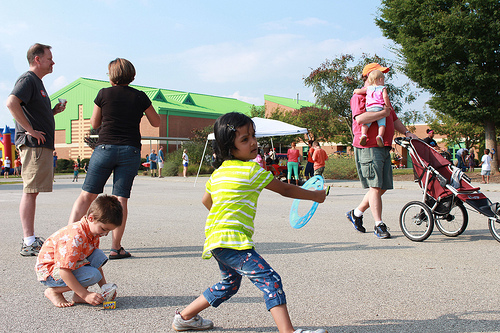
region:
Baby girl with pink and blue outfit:
[361, 68, 391, 152]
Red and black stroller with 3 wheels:
[393, 133, 496, 248]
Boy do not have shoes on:
[38, 191, 128, 311]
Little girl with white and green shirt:
[204, 105, 286, 257]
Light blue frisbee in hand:
[287, 170, 332, 236]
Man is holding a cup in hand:
[7, 44, 70, 256]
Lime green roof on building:
[146, 79, 253, 116]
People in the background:
[283, 138, 331, 180]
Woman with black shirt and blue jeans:
[68, 48, 157, 193]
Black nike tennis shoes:
[344, 204, 397, 241]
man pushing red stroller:
[329, 55, 499, 230]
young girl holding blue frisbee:
[185, 120, 340, 322]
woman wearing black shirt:
[65, 57, 162, 265]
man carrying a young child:
[343, 58, 407, 239]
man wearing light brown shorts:
[3, 37, 65, 258]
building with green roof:
[35, 76, 261, 170]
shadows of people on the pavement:
[121, 219, 488, 331]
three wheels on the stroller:
[402, 194, 497, 235]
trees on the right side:
[301, 3, 488, 167]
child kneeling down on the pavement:
[30, 204, 126, 311]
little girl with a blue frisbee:
[163, 105, 328, 331]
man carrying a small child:
[345, 55, 405, 239]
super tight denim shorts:
[72, 139, 142, 197]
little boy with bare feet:
[26, 191, 130, 313]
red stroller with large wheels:
[390, 128, 499, 248]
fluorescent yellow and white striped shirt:
[187, 156, 274, 258]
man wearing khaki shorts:
[2, 40, 69, 256]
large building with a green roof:
[26, 71, 325, 173]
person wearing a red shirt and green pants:
[277, 138, 305, 187]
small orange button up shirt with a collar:
[24, 217, 100, 284]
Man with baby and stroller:
[345, 59, 496, 247]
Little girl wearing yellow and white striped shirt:
[192, 111, 290, 263]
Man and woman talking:
[8, 43, 160, 188]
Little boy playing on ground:
[28, 193, 137, 313]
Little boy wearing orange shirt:
[25, 189, 120, 280]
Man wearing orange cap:
[356, 53, 392, 84]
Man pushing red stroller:
[351, 56, 496, 248]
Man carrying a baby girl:
[352, 56, 393, 149]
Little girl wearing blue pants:
[171, 107, 346, 332]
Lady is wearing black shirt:
[81, 55, 159, 163]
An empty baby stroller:
[392, 130, 498, 247]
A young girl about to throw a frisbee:
[172, 104, 328, 331]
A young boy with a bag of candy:
[32, 194, 120, 311]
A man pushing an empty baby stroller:
[343, 61, 425, 240]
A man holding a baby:
[342, 58, 417, 240]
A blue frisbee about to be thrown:
[286, 175, 325, 229]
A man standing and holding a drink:
[3, 41, 69, 255]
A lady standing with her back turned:
[68, 55, 163, 267]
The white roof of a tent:
[204, 114, 309, 141]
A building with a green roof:
[45, 72, 355, 176]